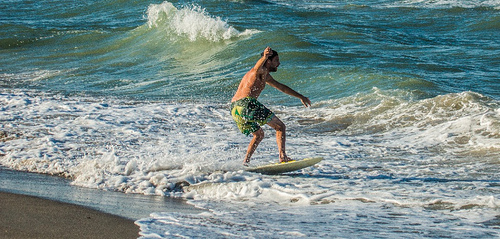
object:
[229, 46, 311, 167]
man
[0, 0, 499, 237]
ocean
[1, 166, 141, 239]
shore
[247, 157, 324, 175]
surfboard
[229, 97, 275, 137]
swim trunks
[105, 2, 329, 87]
wave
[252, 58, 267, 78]
arm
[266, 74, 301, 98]
arm